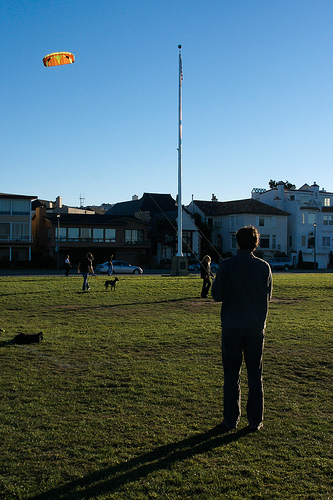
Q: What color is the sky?
A: Blue.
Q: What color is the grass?
A: Green.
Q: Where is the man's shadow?
A: On the ground.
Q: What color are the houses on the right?
A: White.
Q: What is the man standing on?
A: Grass.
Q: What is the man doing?
A: Flying a kite.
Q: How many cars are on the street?
A: 3.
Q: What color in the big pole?
A: White.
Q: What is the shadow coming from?
A: The man's legs.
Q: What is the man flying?
A: A kite.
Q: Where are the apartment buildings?
A: Next to the park.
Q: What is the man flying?
A: A kite.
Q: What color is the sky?
A: Blue.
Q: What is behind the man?
A: A shadow.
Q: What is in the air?
A: Kite.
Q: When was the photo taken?
A: Daytime.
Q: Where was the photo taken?
A: Grassy field.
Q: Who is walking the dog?
A: Man.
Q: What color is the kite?
A: Yellow.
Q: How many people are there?
A: 3.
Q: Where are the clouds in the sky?
A: Gone.